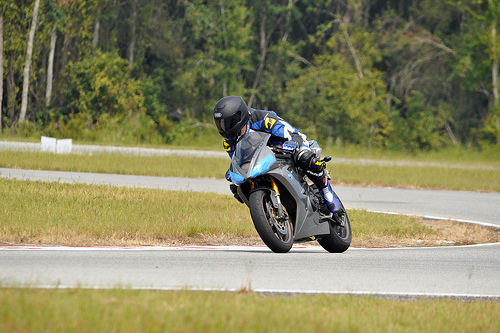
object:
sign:
[56, 137, 71, 154]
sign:
[36, 135, 58, 155]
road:
[0, 136, 498, 177]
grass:
[0, 273, 498, 333]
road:
[0, 165, 499, 224]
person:
[208, 95, 342, 216]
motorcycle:
[229, 123, 354, 253]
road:
[1, 235, 499, 294]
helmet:
[210, 91, 252, 141]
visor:
[209, 110, 242, 135]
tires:
[314, 189, 352, 252]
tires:
[245, 186, 296, 254]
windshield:
[229, 127, 274, 180]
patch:
[260, 116, 277, 133]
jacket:
[222, 107, 307, 162]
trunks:
[17, 0, 40, 122]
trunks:
[44, 28, 57, 111]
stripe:
[243, 153, 279, 182]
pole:
[270, 178, 282, 198]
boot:
[314, 171, 342, 212]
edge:
[1, 239, 499, 258]